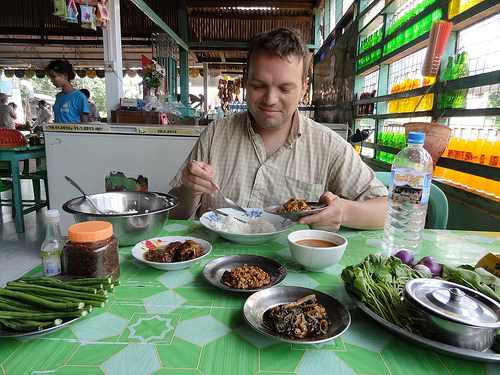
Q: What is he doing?
A: Eating.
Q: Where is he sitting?
A: Table.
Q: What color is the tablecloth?
A: Green.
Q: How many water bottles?
A: One.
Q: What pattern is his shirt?
A: Checker.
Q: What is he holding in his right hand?
A: Spoon.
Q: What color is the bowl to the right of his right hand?
A: Silver.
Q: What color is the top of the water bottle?
A: Blue.